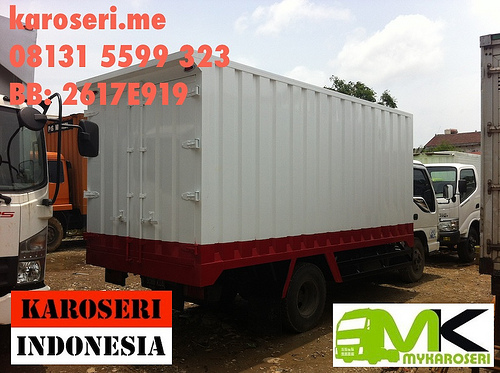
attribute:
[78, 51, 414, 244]
storage box — white, big, red, closed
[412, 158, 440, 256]
truck — white, parked, red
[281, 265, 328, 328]
tire — rubber, black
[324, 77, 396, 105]
tree — green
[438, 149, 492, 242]
truck — white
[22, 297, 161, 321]
letters — black